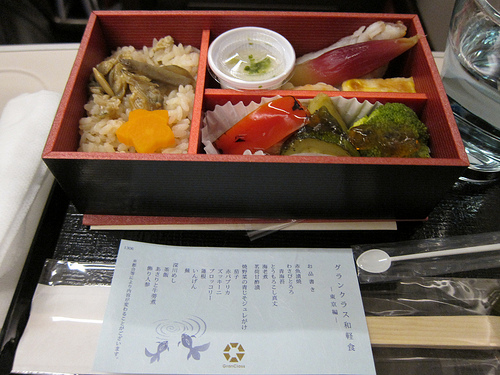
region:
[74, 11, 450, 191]
SQUARE ASIAN STYLE DIVIDER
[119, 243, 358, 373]
WHITE PIECE OF PAPER ON TABLE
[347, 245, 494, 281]
LONG WHITE PLASTIC UTENSIL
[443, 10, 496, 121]
TRANSPARENT GLASS OFF TO THE SIDE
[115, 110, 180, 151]
ORANGE CARROT SHAPED LIKE STAR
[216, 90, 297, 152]
RED TOMATO CUT INTO RECTANGLE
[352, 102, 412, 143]
GREEN VEGITABLE IN RED CONTAINER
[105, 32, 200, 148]
STEAMED WHITE RICE IN CONTAINER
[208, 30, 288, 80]
WHITE PLASTIC CONTAINER WITHIN LARGER TRAY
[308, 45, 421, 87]
UNKNOWN MYSTERY ITEM ON TRAY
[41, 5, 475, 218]
Red and black bento box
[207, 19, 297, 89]
Small round white bowl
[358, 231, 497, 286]
White spoon in a plastic wrapper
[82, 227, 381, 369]
White paper with black writing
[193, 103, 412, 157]
Vegetables on top of white paper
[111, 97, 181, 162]
Orange fruit in a shape of a star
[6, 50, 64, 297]
White towel on the counter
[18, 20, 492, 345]
Food on top of a black tray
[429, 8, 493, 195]
Clear glass with water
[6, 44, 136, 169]
The counter is white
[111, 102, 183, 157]
a yellow star on the rice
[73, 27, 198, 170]
a serving of white rice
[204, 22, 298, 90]
a white plastic container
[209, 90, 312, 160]
a red bell pepper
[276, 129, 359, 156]
a piece of zucchini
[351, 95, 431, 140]
a piece of green broccoli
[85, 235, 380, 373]
a piece of white paper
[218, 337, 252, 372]
a brown logo on the paper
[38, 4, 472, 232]
a red food divider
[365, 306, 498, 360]
a brown piece of wood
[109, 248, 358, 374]
food receipt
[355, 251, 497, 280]
sushi spoon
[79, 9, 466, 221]
bento box black outside with three compartments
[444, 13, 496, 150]
glass of water mostly full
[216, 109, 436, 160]
broccoli, red pepper and zucchini vegetables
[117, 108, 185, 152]
star shaped fruit or vegetable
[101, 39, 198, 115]
white rice underneath fish or anchovies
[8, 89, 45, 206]
white napkin on table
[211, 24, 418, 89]
meat and cheese section of bento box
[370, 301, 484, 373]
wooden utensils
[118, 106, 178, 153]
a yellow star shaped food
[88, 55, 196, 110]
meat in the rice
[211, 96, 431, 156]
a bunch of fried vegetables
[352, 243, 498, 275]
a small plastic spoon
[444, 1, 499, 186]
a tall glass of water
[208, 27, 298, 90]
a plastic sauce cup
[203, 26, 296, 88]
a plastic lid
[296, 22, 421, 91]
a large purple vegetable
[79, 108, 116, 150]
white rice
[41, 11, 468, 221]
A big rectangular bowl of food